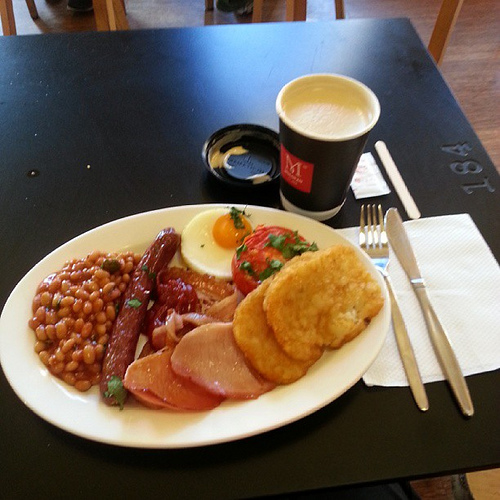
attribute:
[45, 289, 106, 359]
beans — brown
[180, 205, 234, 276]
egg white — egg's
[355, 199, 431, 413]
fork — silver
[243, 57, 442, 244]
cup — black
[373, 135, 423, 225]
stick — small, wooden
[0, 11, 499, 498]
table — black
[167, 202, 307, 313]
egg —  sunny side up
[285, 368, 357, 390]
plate — used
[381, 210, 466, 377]
butter knife — silver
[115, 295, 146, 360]
sausage — long, dark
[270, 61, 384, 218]
cup —  for coffee,  with liquid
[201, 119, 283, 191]
lid — beside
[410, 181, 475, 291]
napkin — white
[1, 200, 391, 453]
plate — full, white